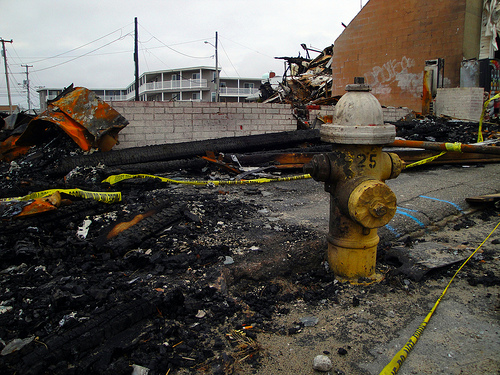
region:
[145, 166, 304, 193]
Yellow police tape strewn on the ground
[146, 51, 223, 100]
The balcony of a building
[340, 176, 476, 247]
Blue paint stripes on a curb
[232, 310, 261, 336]
A cigarette in the ash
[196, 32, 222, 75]
A street lamp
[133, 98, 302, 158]
A concrete block wall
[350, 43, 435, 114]
Graffiti on the side of a building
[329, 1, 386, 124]
A brick wall with a sloped top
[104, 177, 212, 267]
A length of charred wood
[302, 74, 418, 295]
A blackened fire hydrant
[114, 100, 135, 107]
a brick on a wall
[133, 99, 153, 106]
a brick on a wall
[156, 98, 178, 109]
a brick on a wall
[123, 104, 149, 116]
a brick on a wall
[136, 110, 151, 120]
a brick on a wall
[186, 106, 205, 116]
a brick on a wall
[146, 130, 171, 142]
a brick on a wall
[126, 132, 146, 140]
a brick on a wall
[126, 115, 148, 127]
a brick on a wall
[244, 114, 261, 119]
a brick on a wall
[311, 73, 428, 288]
THIS IS A HYDRANT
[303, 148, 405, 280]
the hydrant is yellow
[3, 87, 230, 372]
this is a fire scene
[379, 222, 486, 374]
the yellow stipe for crime scene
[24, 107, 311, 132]
the wall is made of bricks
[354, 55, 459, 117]
this is grey smke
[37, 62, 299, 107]
this is a building in the background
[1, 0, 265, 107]
electricity lines and posts at the background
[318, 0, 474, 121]
the building is made ofbricks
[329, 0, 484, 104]
the building is brown in color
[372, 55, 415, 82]
writing on brick wall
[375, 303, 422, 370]
yellow do not cross tape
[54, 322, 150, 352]
charred remnants from fire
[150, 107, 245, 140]
a brick partition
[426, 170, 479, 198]
asphalt section of street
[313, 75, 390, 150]
top portion of fire hydrant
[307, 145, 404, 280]
bottom portion of fire hydrant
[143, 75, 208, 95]
balcony area in building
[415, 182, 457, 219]
blue marking on street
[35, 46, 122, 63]
several telephone lines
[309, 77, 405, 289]
a fire hydrant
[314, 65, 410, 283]
a yellow fire hydrant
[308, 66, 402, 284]
the left side of the fire hydrant is burnt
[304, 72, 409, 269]
the hydrant has a white top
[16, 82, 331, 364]
burnt ashes and debris on the ground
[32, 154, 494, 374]
yellow caution tape is on the ground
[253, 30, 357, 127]
debris behind the building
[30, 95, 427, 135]
a grey brick wall runs between the two piles of debris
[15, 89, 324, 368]
the area is burnt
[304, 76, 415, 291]
the fire hydrant is number 25